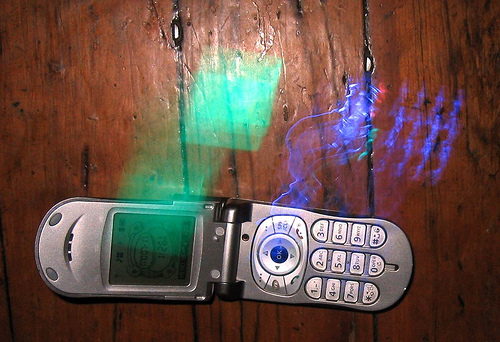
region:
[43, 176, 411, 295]
cell phone on table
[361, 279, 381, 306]
button on cell phone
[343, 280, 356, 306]
button on cell phone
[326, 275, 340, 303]
button on cell phone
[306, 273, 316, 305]
button on cell phone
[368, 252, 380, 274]
button on cell phone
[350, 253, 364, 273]
button on cell phone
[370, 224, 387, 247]
button on cell phone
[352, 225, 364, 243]
button on cell phone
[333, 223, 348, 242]
button on cell phone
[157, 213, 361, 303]
a grey mobile phone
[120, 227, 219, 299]
a grey mobile phone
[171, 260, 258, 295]
a grey mobile phone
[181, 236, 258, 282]
a grey mobile phone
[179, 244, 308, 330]
a grey mobile phone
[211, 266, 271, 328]
a grey mobile phone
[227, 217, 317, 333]
a grey mobile phone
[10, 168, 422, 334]
Cell phone on table top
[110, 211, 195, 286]
;Screen of cell phone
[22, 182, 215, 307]
top part of cell phone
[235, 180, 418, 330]
Bottom part of cell phone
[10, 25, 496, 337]
Wood table cell phone is sitting on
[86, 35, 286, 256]
Green imprint of something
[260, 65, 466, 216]
Purple imprint of a paw?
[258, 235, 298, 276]
OK button on cell phone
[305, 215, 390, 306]
Numbers and letters on cell phone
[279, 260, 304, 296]
Answer button on cell phone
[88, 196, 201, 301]
A green and black phone screen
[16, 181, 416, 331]
An old silver flip phone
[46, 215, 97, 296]
The ear speaker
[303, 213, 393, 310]
The number buttons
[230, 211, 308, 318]
Answer, hang up, okay, and other buttons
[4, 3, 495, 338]
A wooden table that the phone is sitting on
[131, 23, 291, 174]
A blurry green screen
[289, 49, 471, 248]
The blur from the button lights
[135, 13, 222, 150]
A crack in the wooden table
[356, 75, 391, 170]
Red and green blurs from the buttons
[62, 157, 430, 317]
light grey cell phone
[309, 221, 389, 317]
small buttons on phone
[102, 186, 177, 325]
small display screen on phone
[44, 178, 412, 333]
phone sits on table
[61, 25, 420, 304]
table is brown and wooden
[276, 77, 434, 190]
blue reflection from phone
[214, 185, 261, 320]
silver hinge on phone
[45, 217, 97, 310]
small speaker on phone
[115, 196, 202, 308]
LCD screen on phone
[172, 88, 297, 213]
green reflection from phone